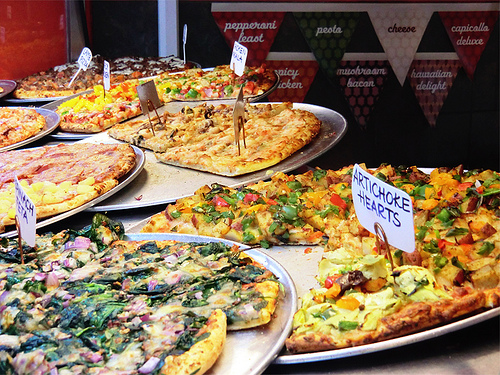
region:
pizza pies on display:
[5, 14, 476, 361]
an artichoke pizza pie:
[286, 212, 465, 314]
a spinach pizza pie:
[47, 219, 251, 354]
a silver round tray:
[57, 79, 354, 236]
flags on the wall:
[208, 0, 485, 121]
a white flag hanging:
[354, 0, 450, 95]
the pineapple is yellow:
[52, 78, 112, 115]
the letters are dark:
[314, 155, 419, 241]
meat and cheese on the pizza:
[53, 46, 173, 77]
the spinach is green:
[65, 220, 257, 320]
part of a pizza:
[194, 325, 222, 354]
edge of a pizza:
[311, 318, 356, 354]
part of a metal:
[374, 237, 390, 257]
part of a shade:
[438, 338, 461, 355]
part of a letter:
[377, 192, 404, 229]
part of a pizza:
[186, 326, 210, 353]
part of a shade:
[436, 347, 458, 364]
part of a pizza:
[359, 293, 401, 327]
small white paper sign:
[351, 166, 415, 255]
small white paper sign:
[229, 83, 248, 141]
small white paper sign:
[231, 38, 248, 76]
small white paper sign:
[134, 79, 162, 110]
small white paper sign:
[182, 24, 189, 44]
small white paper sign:
[103, 59, 112, 92]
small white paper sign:
[78, 43, 93, 71]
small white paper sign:
[11, 173, 36, 250]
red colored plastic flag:
[258, 51, 318, 101]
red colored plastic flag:
[211, 13, 281, 68]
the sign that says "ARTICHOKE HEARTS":
[351, 163, 413, 250]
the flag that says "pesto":
[293, 11, 355, 83]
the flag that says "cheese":
[365, 7, 426, 82]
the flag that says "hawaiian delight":
[408, 50, 460, 125]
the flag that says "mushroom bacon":
[335, 52, 392, 128]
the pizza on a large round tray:
[122, 152, 499, 364]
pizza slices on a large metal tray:
[83, 97, 345, 208]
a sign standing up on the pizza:
[348, 162, 420, 272]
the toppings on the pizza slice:
[197, 190, 271, 229]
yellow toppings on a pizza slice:
[0, 183, 91, 218]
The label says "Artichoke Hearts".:
[349, 164, 417, 257]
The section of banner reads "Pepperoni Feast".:
[212, 1, 287, 69]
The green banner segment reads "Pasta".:
[292, 5, 366, 79]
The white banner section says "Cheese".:
[367, 3, 433, 84]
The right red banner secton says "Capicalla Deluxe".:
[439, 3, 497, 75]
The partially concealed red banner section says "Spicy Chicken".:
[260, 53, 317, 124]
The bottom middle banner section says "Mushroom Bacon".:
[330, 53, 392, 129]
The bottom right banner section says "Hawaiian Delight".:
[405, 52, 462, 128]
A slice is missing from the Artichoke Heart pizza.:
[142, 182, 329, 357]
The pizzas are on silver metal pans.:
[1, 55, 492, 374]